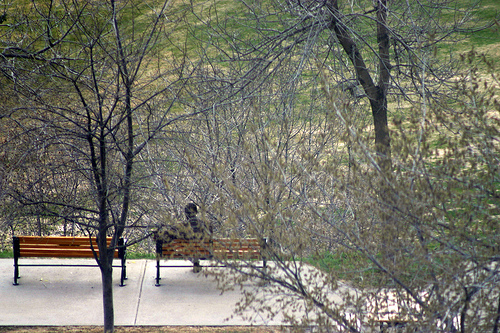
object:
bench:
[9, 232, 129, 289]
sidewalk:
[0, 250, 500, 326]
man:
[150, 197, 219, 276]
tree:
[0, 1, 296, 332]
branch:
[142, 56, 209, 148]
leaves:
[92, 40, 142, 63]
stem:
[85, 268, 131, 329]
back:
[11, 235, 122, 260]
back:
[158, 231, 268, 261]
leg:
[118, 246, 128, 289]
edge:
[118, 248, 129, 274]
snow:
[0, 258, 229, 322]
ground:
[0, 270, 209, 332]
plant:
[306, 1, 404, 286]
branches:
[104, 74, 187, 138]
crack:
[132, 259, 149, 329]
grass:
[210, 22, 277, 66]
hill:
[1, 0, 500, 107]